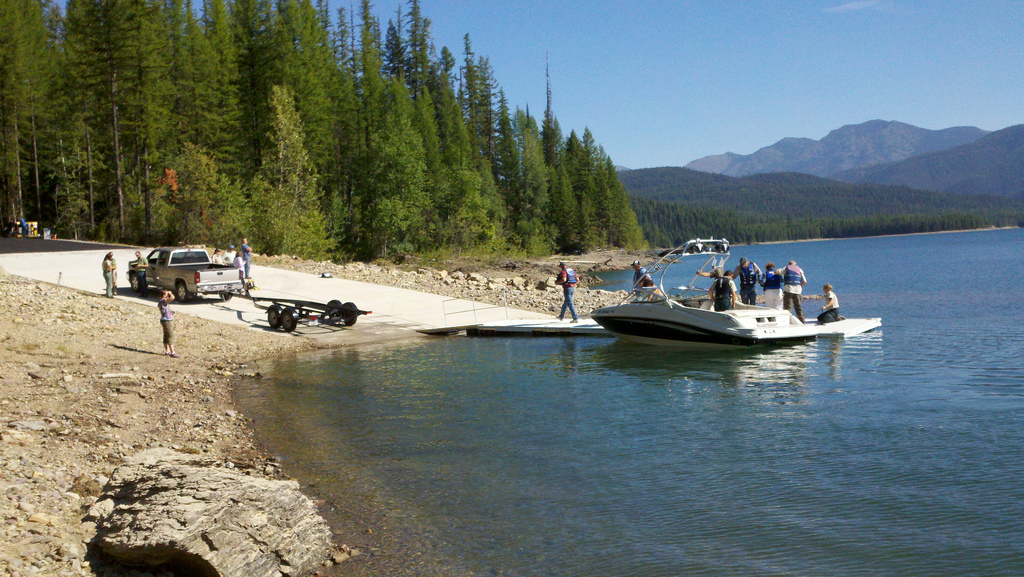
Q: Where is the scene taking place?
A: At a boat ramp.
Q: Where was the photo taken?
A: Near a boat ramp.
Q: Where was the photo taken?
A: At a lake.